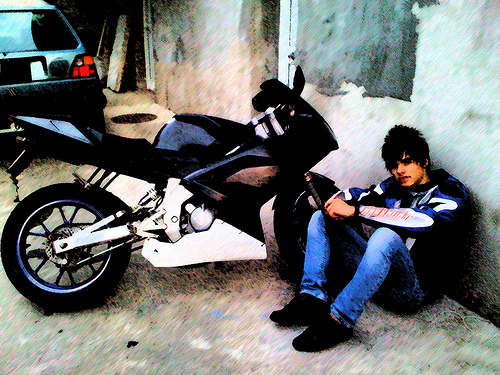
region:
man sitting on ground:
[228, 74, 496, 360]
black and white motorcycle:
[0, 59, 460, 356]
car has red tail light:
[60, 54, 104, 93]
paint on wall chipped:
[288, 1, 475, 138]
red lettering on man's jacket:
[348, 196, 438, 232]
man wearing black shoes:
[255, 271, 367, 371]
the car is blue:
[0, 0, 144, 151]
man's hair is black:
[345, 107, 466, 192]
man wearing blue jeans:
[285, 185, 459, 350]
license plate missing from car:
[0, 51, 62, 89]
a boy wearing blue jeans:
[283, 139, 449, 339]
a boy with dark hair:
[373, 122, 441, 193]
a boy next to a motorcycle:
[42, 72, 474, 342]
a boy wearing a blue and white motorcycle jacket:
[321, 103, 479, 278]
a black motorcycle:
[28, 85, 335, 344]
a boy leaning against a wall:
[279, 35, 481, 331]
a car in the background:
[7, 12, 157, 105]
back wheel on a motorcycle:
[6, 172, 136, 317]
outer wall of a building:
[290, 18, 475, 241]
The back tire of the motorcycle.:
[4, 180, 144, 308]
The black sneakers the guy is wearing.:
[266, 289, 361, 359]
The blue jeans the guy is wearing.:
[301, 203, 411, 327]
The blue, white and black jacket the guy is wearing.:
[339, 160, 471, 270]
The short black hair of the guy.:
[372, 120, 434, 170]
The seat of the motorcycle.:
[4, 109, 144, 162]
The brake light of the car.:
[61, 52, 103, 84]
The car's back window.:
[4, 11, 79, 49]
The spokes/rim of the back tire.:
[18, 208, 112, 285]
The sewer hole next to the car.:
[108, 104, 163, 135]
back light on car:
[63, 52, 104, 80]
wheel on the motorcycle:
[26, 219, 115, 269]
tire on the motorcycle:
[0, 207, 122, 301]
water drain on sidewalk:
[114, 108, 161, 130]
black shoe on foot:
[293, 328, 358, 348]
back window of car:
[2, 17, 67, 45]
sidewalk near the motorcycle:
[152, 320, 256, 362]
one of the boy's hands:
[329, 195, 355, 223]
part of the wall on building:
[412, 25, 476, 110]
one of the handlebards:
[259, 75, 279, 116]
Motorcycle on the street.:
[7, 79, 359, 314]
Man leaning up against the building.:
[264, 120, 486, 355]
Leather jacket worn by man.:
[326, 173, 477, 305]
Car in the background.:
[1, 2, 115, 155]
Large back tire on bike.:
[0, 173, 137, 315]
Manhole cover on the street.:
[109, 103, 161, 135]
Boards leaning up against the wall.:
[86, 4, 142, 99]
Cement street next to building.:
[1, 86, 493, 366]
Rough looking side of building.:
[80, 3, 496, 328]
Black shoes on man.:
[265, 293, 356, 353]